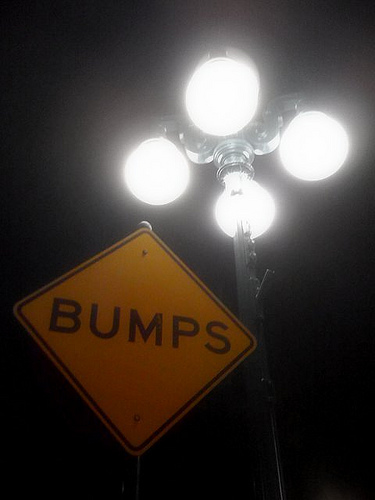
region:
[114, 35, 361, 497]
The streetlamp is on.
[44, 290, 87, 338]
The letter is black.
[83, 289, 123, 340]
The letter is black.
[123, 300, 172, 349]
The letter is black.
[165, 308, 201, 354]
The letter is black.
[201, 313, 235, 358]
The letter is black.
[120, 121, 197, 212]
The light globe is round.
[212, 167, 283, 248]
The light globe is round.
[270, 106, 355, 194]
The light globe is round.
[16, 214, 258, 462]
The sign is diamond shaped.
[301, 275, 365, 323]
The sky is black.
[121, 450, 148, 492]
The sign pole is dark in color.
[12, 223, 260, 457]
The sign is yellow and black.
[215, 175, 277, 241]
The light bulb is shining.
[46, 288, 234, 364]
The sign word is in black.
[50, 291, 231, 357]
The sign is in English.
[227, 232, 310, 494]
The light pole is dark in color.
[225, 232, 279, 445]
The light pole is tall.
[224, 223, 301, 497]
The light pole is made of metal.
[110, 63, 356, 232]
four lights in photo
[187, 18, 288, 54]
light coming from lamp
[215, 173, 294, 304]
pole in the photo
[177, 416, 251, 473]
black background of the photo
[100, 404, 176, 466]
bottom of the sign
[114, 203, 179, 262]
top of the sign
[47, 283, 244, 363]
word on the sign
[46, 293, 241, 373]
yellow and black sign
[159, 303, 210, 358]
the letter P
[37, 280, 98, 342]
the letter B on sign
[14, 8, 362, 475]
Picture taken in the evening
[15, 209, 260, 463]
This is a yellow sign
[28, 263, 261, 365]
The sign says bumps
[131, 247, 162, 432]
Sign fastened by two bolts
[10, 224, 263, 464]
Sign shaped like a diamond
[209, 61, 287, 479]
Tall lamp post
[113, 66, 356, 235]
Four lights on the lamp post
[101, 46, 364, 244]
All of the lights are turned on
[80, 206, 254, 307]
Light shining on the sign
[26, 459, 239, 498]
Background of the image is black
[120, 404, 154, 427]
bolt in the sign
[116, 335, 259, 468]
edge of the sign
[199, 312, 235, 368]
s on the sign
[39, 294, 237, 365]
letters on the sign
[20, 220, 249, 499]
sign on a pole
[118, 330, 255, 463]
dark boarder on the sign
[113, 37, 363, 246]
lights above the sign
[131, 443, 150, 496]
pole for the sign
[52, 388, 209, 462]
bottom of the sign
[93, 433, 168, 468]
tip of the sign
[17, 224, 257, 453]
The sign is yellow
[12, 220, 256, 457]
The sign says bumps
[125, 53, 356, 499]
THE STREET LIGHT OVER THE SIGN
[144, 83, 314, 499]
tHE POST OF THE STREETLIGHTS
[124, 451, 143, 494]
The pole for the sign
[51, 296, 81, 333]
sign has a letter